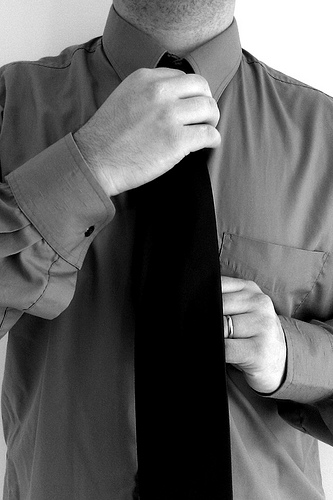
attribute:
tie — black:
[136, 71, 222, 479]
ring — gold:
[224, 317, 240, 341]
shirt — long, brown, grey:
[7, 57, 332, 447]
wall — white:
[4, 4, 333, 110]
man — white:
[32, 7, 314, 495]